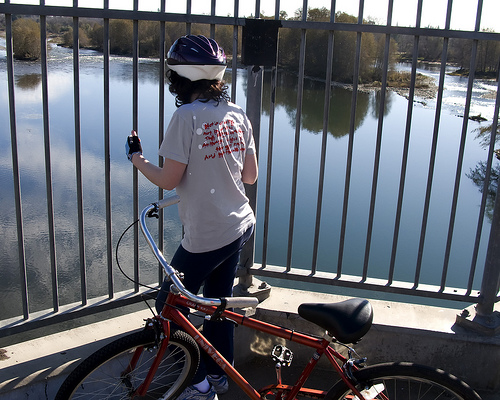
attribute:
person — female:
[126, 34, 258, 398]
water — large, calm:
[0, 31, 499, 321]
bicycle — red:
[54, 198, 482, 397]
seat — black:
[299, 298, 374, 343]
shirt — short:
[159, 98, 257, 253]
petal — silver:
[270, 341, 293, 368]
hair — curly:
[167, 69, 230, 108]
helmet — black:
[163, 34, 229, 83]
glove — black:
[124, 136, 144, 161]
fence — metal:
[2, 0, 500, 340]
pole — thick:
[233, 18, 283, 301]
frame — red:
[122, 286, 390, 398]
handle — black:
[150, 192, 179, 218]